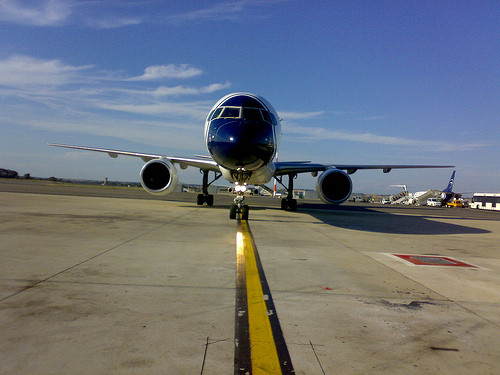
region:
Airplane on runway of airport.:
[42, 89, 461, 228]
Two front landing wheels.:
[224, 203, 254, 222]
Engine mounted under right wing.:
[136, 157, 180, 198]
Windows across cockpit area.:
[203, 104, 275, 126]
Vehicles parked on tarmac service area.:
[425, 194, 465, 213]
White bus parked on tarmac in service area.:
[467, 190, 499, 216]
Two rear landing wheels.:
[193, 185, 219, 210]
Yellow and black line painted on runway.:
[223, 235, 308, 373]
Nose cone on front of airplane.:
[211, 122, 269, 161]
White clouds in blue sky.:
[12, 38, 182, 130]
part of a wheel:
[226, 199, 238, 214]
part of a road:
[292, 293, 316, 321]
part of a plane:
[362, 163, 375, 173]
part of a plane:
[239, 183, 245, 193]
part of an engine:
[150, 178, 155, 184]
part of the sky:
[389, 143, 394, 148]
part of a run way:
[242, 291, 259, 323]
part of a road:
[136, 280, 155, 297]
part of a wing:
[343, 161, 348, 170]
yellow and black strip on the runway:
[230, 223, 296, 374]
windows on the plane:
[216, 99, 260, 120]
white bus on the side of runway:
[470, 185, 497, 206]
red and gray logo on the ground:
[387, 243, 475, 283]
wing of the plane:
[43, 130, 138, 172]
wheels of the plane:
[188, 190, 220, 212]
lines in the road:
[46, 264, 137, 308]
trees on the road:
[1, 162, 22, 178]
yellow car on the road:
[446, 195, 461, 210]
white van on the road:
[425, 195, 440, 207]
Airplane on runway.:
[45, 90, 454, 218]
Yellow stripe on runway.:
[241, 215, 281, 372]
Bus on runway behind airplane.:
[462, 187, 497, 212]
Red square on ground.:
[391, 251, 478, 266]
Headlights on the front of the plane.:
[230, 175, 255, 200]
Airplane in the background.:
[410, 168, 456, 203]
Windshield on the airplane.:
[205, 105, 277, 122]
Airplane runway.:
[0, 190, 496, 372]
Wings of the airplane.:
[45, 141, 452, 177]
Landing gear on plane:
[197, 170, 299, 219]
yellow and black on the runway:
[228, 223, 292, 373]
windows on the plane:
[210, 108, 272, 124]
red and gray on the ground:
[384, 235, 479, 280]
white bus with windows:
[470, 188, 499, 215]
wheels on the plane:
[190, 190, 217, 207]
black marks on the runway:
[377, 290, 459, 331]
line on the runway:
[46, 268, 194, 300]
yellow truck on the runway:
[444, 198, 464, 208]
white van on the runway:
[427, 196, 441, 207]